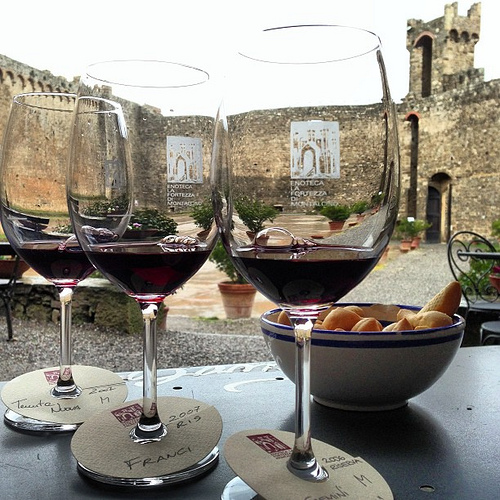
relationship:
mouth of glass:
[262, 25, 381, 51] [211, 23, 401, 498]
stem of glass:
[288, 311, 321, 472] [211, 23, 401, 498]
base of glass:
[221, 461, 389, 500] [211, 23, 401, 498]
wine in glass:
[230, 253, 382, 304] [211, 23, 401, 498]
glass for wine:
[211, 23, 401, 498] [230, 253, 382, 304]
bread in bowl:
[277, 282, 464, 329] [258, 303, 465, 413]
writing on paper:
[122, 447, 193, 470] [70, 397, 222, 477]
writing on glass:
[290, 180, 329, 208] [211, 23, 401, 498]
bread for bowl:
[277, 282, 464, 329] [258, 303, 465, 413]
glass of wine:
[211, 23, 401, 498] [230, 253, 382, 304]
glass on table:
[211, 23, 401, 498] [3, 342, 500, 499]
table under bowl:
[3, 342, 500, 499] [258, 303, 465, 413]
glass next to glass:
[211, 23, 401, 498] [70, 59, 218, 485]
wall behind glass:
[385, 0, 500, 248] [211, 23, 401, 498]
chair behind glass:
[446, 230, 498, 328] [211, 23, 401, 498]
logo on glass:
[289, 122, 340, 178] [211, 23, 401, 498]